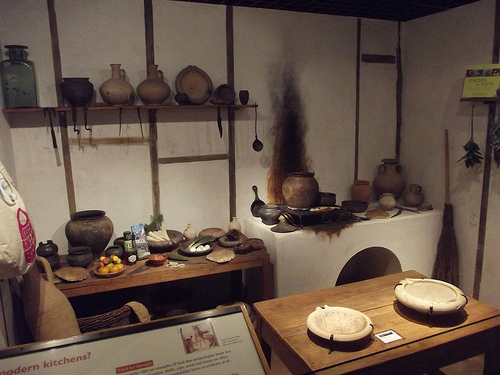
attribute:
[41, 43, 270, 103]
pots — arranged, black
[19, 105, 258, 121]
shelf — wood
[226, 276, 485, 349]
table — wood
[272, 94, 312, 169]
stain — black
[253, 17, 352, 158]
wall — white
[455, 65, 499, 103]
book — yellow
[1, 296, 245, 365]
sign — informative, descriptive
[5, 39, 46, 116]
jar — glass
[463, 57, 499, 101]
sign — yellow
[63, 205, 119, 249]
bowl — brown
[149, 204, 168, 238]
carrot — white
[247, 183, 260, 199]
handle — black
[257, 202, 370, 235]
stove — black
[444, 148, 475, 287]
sweeper — brown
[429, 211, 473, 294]
broom — straw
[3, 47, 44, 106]
bottle — glass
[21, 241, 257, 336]
table — wooden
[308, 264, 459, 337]
plates — clay